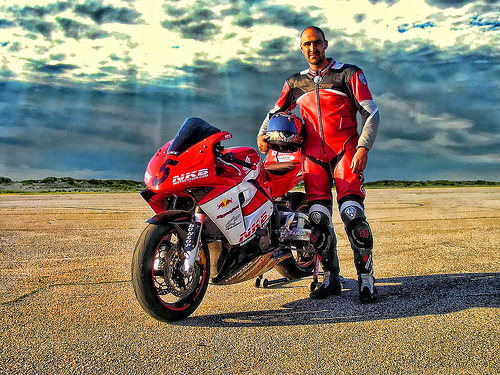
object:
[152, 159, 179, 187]
5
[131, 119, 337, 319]
bike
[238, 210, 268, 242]
nkb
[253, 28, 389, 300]
man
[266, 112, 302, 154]
helmet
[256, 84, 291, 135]
arm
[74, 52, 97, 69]
light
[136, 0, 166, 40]
clouds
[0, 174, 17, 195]
mountains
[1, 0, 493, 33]
sky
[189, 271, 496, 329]
marks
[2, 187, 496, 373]
pavement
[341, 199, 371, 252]
knee pads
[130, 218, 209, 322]
tire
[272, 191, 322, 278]
wheel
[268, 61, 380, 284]
dirt bike suit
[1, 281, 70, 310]
crack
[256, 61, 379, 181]
motorcycle jacket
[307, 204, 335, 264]
knee pad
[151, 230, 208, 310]
red rim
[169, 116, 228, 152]
windshield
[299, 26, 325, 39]
short hair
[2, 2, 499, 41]
cloudy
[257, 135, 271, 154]
hand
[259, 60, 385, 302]
outfit